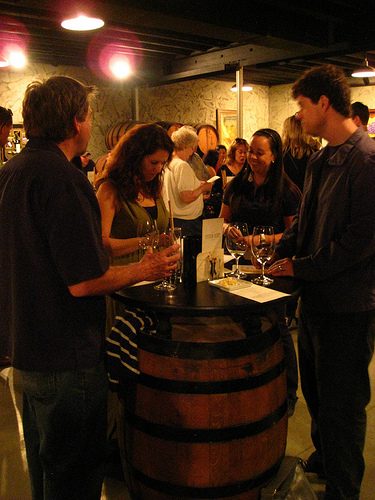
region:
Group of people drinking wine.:
[17, 50, 367, 413]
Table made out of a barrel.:
[105, 276, 289, 496]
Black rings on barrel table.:
[127, 324, 288, 495]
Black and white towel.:
[97, 297, 166, 389]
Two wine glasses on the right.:
[223, 212, 281, 293]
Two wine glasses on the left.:
[133, 214, 191, 298]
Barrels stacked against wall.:
[96, 94, 238, 170]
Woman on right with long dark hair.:
[222, 123, 302, 258]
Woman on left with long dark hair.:
[94, 109, 186, 260]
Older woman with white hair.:
[165, 123, 212, 247]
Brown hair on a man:
[16, 71, 122, 189]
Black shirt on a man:
[1, 130, 134, 354]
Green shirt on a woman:
[93, 128, 220, 280]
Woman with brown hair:
[216, 135, 305, 249]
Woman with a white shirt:
[164, 122, 221, 232]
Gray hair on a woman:
[166, 124, 204, 156]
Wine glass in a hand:
[134, 231, 184, 300]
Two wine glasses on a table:
[222, 213, 282, 295]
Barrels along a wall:
[107, 110, 224, 155]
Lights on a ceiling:
[33, 7, 156, 90]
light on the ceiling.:
[55, 12, 104, 33]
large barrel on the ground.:
[195, 353, 260, 422]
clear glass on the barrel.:
[228, 229, 247, 274]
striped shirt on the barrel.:
[116, 317, 142, 364]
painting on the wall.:
[220, 111, 237, 142]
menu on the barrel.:
[202, 223, 220, 251]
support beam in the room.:
[233, 74, 241, 128]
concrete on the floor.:
[293, 422, 301, 447]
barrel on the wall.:
[108, 122, 128, 131]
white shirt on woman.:
[168, 169, 185, 189]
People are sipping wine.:
[74, 167, 180, 294]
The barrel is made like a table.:
[135, 338, 273, 484]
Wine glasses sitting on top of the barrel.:
[218, 226, 303, 299]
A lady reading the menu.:
[165, 125, 215, 230]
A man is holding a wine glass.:
[53, 219, 190, 294]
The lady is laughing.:
[226, 128, 289, 228]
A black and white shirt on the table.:
[109, 301, 151, 385]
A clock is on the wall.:
[189, 111, 232, 154]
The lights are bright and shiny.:
[95, 39, 175, 88]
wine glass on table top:
[248, 224, 282, 286]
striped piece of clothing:
[103, 305, 163, 385]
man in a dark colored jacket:
[271, 62, 374, 499]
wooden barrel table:
[107, 267, 300, 497]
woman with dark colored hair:
[88, 124, 177, 263]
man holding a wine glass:
[1, 72, 185, 499]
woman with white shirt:
[164, 124, 221, 265]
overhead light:
[57, 6, 112, 40]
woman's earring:
[268, 150, 277, 164]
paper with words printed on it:
[194, 216, 228, 280]